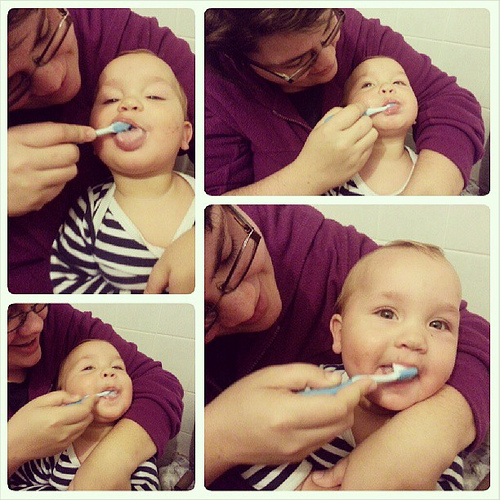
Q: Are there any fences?
A: No, there are no fences.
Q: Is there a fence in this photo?
A: No, there are no fences.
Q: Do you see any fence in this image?
A: No, there are no fences.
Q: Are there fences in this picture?
A: No, there are no fences.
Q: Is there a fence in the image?
A: No, there are no fences.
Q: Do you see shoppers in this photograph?
A: No, there are no shoppers.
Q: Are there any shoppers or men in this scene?
A: No, there are no shoppers or men.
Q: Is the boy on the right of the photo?
A: Yes, the boy is on the right of the image.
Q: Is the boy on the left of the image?
A: No, the boy is on the right of the image.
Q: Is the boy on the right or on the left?
A: The boy is on the right of the image.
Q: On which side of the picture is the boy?
A: The boy is on the right of the image.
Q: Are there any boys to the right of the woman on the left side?
A: Yes, there is a boy to the right of the woman.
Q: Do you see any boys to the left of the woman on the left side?
A: No, the boy is to the right of the woman.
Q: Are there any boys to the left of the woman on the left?
A: No, the boy is to the right of the woman.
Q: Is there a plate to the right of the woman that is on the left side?
A: No, there is a boy to the right of the woman.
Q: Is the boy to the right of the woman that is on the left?
A: Yes, the boy is to the right of the woman.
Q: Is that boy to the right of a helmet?
A: No, the boy is to the right of the woman.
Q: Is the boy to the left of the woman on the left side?
A: No, the boy is to the right of the woman.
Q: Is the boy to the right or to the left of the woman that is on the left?
A: The boy is to the right of the woman.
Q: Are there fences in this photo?
A: No, there are no fences.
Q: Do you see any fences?
A: No, there are no fences.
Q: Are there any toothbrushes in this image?
A: Yes, there is a toothbrush.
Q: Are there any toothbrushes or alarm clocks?
A: Yes, there is a toothbrush.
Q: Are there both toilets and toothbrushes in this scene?
A: No, there is a toothbrush but no toilets.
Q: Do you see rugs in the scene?
A: No, there are no rugs.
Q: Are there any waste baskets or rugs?
A: No, there are no rugs or waste baskets.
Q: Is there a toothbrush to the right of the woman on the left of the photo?
A: Yes, there is a toothbrush to the right of the woman.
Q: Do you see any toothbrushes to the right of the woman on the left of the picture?
A: Yes, there is a toothbrush to the right of the woman.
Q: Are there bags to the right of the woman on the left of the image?
A: No, there is a toothbrush to the right of the woman.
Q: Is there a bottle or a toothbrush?
A: Yes, there is a toothbrush.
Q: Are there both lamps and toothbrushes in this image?
A: No, there is a toothbrush but no lamps.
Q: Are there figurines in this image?
A: No, there are no figurines.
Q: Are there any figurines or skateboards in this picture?
A: No, there are no figurines or skateboards.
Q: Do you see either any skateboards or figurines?
A: No, there are no figurines or skateboards.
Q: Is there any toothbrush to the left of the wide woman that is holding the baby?
A: Yes, there is a toothbrush to the left of the woman.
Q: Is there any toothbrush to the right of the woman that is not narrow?
A: No, the toothbrush is to the left of the woman.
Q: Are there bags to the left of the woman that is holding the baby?
A: No, there is a toothbrush to the left of the woman.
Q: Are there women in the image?
A: Yes, there is a woman.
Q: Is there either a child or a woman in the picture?
A: Yes, there is a woman.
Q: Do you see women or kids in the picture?
A: Yes, there is a woman.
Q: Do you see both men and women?
A: No, there is a woman but no men.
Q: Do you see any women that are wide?
A: Yes, there is a wide woman.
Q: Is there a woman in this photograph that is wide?
A: Yes, there is a woman that is wide.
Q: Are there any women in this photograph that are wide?
A: Yes, there is a woman that is wide.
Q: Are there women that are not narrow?
A: Yes, there is a wide woman.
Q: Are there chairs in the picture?
A: No, there are no chairs.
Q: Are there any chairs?
A: No, there are no chairs.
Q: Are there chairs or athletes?
A: No, there are no chairs or athletes.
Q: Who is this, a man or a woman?
A: This is a woman.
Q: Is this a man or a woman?
A: This is a woman.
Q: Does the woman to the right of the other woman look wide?
A: Yes, the woman is wide.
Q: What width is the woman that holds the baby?
A: The woman is wide.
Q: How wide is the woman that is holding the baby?
A: The woman is wide.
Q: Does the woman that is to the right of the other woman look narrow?
A: No, the woman is wide.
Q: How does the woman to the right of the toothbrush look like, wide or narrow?
A: The woman is wide.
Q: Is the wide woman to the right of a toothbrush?
A: Yes, the woman is to the right of a toothbrush.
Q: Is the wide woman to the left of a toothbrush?
A: No, the woman is to the right of a toothbrush.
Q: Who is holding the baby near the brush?
A: The woman is holding the baby.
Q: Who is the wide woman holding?
A: The woman is holding the baby.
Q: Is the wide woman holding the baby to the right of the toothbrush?
A: Yes, the woman is holding the baby.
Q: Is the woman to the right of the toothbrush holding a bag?
A: No, the woman is holding the baby.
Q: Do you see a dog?
A: No, there are no dogs.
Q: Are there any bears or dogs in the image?
A: No, there are no dogs or bears.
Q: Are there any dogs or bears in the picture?
A: No, there are no dogs or bears.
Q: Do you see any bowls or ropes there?
A: No, there are no ropes or bowls.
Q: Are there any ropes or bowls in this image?
A: No, there are no ropes or bowls.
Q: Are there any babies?
A: Yes, there is a baby.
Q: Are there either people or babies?
A: Yes, there is a baby.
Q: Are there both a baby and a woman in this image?
A: Yes, there are both a baby and a woman.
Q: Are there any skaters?
A: No, there are no skaters.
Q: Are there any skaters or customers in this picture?
A: No, there are no skaters or customers.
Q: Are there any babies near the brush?
A: Yes, there is a baby near the brush.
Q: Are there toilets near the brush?
A: No, there is a baby near the brush.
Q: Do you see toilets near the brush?
A: No, there is a baby near the brush.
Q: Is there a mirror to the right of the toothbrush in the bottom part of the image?
A: No, there is a baby to the right of the toothbrush.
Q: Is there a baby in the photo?
A: Yes, there is a baby.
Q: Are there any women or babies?
A: Yes, there is a baby.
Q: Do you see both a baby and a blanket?
A: No, there is a baby but no blankets.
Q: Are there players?
A: No, there are no players.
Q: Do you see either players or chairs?
A: No, there are no players or chairs.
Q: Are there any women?
A: Yes, there is a woman.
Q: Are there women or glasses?
A: Yes, there is a woman.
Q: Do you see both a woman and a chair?
A: No, there is a woman but no chairs.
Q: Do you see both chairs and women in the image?
A: No, there is a woman but no chairs.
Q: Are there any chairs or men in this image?
A: No, there are no chairs or men.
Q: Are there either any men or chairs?
A: No, there are no chairs or men.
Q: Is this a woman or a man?
A: This is a woman.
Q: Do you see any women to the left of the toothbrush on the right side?
A: Yes, there is a woman to the left of the toothbrush.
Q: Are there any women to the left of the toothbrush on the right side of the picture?
A: Yes, there is a woman to the left of the toothbrush.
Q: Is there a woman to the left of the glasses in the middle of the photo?
A: Yes, there is a woman to the left of the glasses.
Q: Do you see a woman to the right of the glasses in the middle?
A: No, the woman is to the left of the glasses.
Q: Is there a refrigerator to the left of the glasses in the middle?
A: No, there is a woman to the left of the glasses.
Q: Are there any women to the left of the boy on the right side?
A: Yes, there is a woman to the left of the boy.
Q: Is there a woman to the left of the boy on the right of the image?
A: Yes, there is a woman to the left of the boy.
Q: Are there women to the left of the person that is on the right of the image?
A: Yes, there is a woman to the left of the boy.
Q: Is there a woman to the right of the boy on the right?
A: No, the woman is to the left of the boy.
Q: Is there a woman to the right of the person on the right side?
A: No, the woman is to the left of the boy.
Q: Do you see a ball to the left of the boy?
A: No, there is a woman to the left of the boy.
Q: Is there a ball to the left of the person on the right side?
A: No, there is a woman to the left of the boy.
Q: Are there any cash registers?
A: No, there are no cash registers.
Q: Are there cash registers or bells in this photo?
A: No, there are no cash registers or bells.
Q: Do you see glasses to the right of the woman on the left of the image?
A: Yes, there are glasses to the right of the woman.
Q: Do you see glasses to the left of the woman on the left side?
A: No, the glasses are to the right of the woman.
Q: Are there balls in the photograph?
A: No, there are no balls.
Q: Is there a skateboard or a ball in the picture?
A: No, there are no balls or skateboards.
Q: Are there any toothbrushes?
A: Yes, there is a toothbrush.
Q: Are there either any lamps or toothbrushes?
A: Yes, there is a toothbrush.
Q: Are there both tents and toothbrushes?
A: No, there is a toothbrush but no tents.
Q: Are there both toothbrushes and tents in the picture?
A: No, there is a toothbrush but no tents.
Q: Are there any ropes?
A: No, there are no ropes.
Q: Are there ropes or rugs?
A: No, there are no ropes or rugs.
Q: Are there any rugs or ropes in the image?
A: No, there are no ropes or rugs.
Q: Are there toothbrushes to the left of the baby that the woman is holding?
A: Yes, there is a toothbrush to the left of the baby.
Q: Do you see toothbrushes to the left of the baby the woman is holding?
A: Yes, there is a toothbrush to the left of the baby.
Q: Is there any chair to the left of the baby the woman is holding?
A: No, there is a toothbrush to the left of the baby.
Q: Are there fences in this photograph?
A: No, there are no fences.